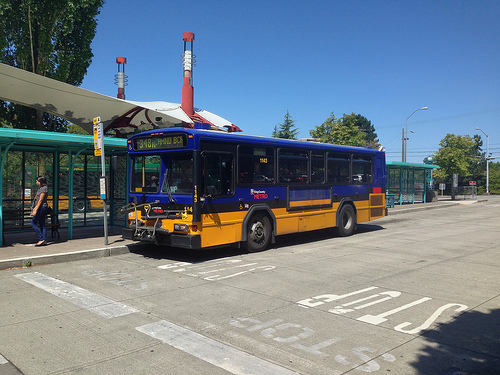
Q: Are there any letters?
A: Yes, there are letters.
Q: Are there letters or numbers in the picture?
A: Yes, there are letters.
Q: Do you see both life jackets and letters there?
A: No, there are letters but no life jackets.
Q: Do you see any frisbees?
A: No, there are no frisbees.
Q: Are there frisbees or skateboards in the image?
A: No, there are no frisbees or skateboards.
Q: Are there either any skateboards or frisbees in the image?
A: No, there are no frisbees or skateboards.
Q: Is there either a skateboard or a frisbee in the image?
A: No, there are no frisbees or skateboards.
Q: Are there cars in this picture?
A: No, there are no cars.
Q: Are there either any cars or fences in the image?
A: No, there are no cars or fences.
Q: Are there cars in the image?
A: No, there are no cars.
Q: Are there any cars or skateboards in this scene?
A: No, there are no cars or skateboards.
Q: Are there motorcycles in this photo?
A: No, there are no motorcycles.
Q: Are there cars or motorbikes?
A: No, there are no motorbikes or cars.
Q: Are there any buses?
A: Yes, there is a bus.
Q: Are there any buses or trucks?
A: Yes, there is a bus.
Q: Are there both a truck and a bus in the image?
A: No, there is a bus but no trucks.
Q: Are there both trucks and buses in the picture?
A: No, there is a bus but no trucks.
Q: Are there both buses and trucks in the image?
A: No, there is a bus but no trucks.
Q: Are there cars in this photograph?
A: No, there are no cars.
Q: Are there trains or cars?
A: No, there are no cars or trains.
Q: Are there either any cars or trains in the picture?
A: No, there are no cars or trains.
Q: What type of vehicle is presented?
A: The vehicle is a bus.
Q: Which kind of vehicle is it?
A: The vehicle is a bus.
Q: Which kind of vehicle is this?
A: This is a bus.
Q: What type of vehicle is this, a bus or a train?
A: This is a bus.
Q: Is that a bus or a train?
A: That is a bus.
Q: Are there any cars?
A: No, there are no cars.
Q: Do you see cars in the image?
A: No, there are no cars.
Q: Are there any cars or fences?
A: No, there are no cars or fences.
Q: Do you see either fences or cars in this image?
A: No, there are no cars or fences.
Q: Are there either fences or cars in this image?
A: No, there are no cars or fences.